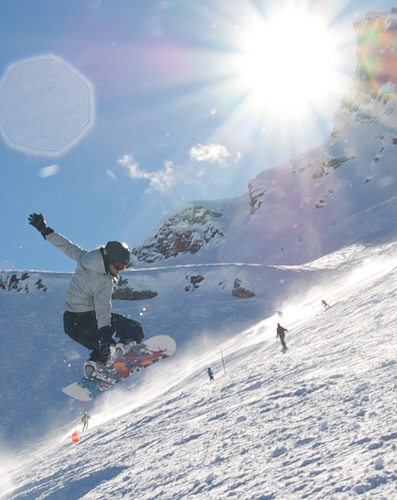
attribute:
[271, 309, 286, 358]
people — walking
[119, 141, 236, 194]
clouds — white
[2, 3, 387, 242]
sky — blue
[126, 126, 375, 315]
mountain — rocky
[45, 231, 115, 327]
jacket — white 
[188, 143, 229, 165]
clouds —  white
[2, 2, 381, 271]
sky — blue,  blue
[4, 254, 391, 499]
snow — rough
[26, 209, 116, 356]
gloves — black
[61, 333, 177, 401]
board — white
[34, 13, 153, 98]
sky — blue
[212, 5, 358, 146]
sun — yellow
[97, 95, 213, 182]
clouds — low, lying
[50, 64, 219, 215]
clouds — white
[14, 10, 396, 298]
sky — blue 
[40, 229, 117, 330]
jacket — white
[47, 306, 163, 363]
pants — black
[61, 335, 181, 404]
snowboard — colorful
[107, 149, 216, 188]
clouds — white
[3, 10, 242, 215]
sky — blue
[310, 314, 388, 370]
snow — bright white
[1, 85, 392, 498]
snow — appearing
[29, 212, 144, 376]
person — wearing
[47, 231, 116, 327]
coat — blue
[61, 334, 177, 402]
surfboard — decorated bottom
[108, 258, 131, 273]
goggles — pair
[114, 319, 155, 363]
person — snow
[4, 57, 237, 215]
clouds — white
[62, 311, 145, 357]
pants — black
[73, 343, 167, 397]
designs — multi color